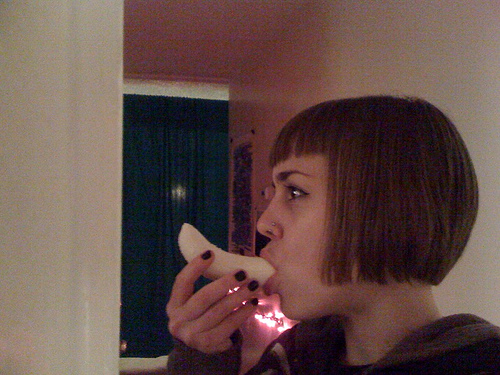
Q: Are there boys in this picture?
A: No, there are no boys.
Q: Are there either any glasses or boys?
A: No, there are no boys or glasses.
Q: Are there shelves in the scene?
A: No, there are no shelves.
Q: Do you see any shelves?
A: No, there are no shelves.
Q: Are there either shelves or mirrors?
A: No, there are no shelves or mirrors.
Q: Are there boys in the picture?
A: No, there are no boys.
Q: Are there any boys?
A: No, there are no boys.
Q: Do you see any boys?
A: No, there are no boys.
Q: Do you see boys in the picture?
A: No, there are no boys.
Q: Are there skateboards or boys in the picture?
A: No, there are no boys or skateboards.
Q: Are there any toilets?
A: No, there are no toilets.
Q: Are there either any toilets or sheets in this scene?
A: No, there are no toilets or sheets.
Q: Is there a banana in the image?
A: Yes, there is a banana.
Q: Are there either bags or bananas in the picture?
A: Yes, there is a banana.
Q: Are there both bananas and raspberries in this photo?
A: No, there is a banana but no raspberries.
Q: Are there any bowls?
A: No, there are no bowls.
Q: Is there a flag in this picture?
A: No, there are no flags.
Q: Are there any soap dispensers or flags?
A: No, there are no flags or soap dispensers.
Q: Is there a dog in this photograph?
A: No, there are no dogs.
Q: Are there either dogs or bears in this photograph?
A: No, there are no dogs or bears.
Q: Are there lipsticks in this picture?
A: No, there are no lipsticks.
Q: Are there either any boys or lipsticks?
A: No, there are no lipsticks or boys.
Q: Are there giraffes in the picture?
A: No, there are no giraffes.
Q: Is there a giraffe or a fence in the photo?
A: No, there are no giraffes or fences.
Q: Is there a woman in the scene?
A: Yes, there is a woman.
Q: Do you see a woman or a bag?
A: Yes, there is a woman.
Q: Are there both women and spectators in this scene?
A: No, there is a woman but no spectators.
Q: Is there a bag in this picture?
A: No, there are no bags.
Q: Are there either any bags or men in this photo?
A: No, there are no bags or men.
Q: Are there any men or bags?
A: No, there are no bags or men.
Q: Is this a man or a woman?
A: This is a woman.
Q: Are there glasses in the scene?
A: No, there are no glasses.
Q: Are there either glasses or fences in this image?
A: No, there are no glasses or fences.